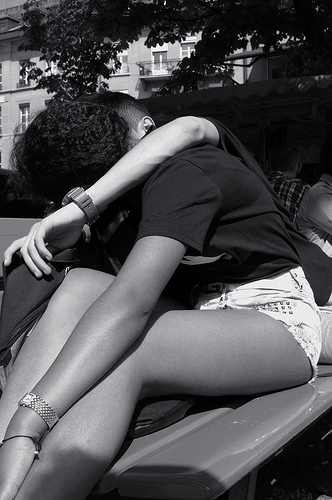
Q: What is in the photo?
A: People.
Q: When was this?
A: Daytime.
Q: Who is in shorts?
A: The lady.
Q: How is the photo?
A: Clear.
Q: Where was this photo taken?
A: Outside an apartment complex.